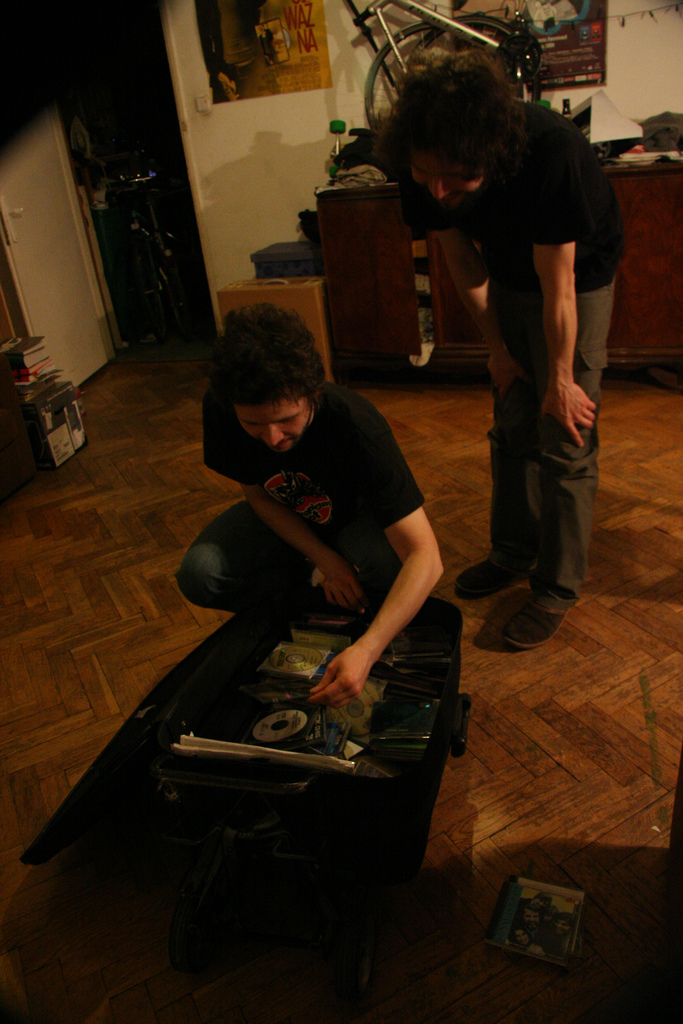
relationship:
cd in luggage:
[253, 710, 308, 743] [251, 608, 444, 769]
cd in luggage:
[258, 640, 331, 681] [229, 618, 442, 758]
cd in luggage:
[258, 640, 331, 681] [228, 587, 462, 820]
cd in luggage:
[195, 589, 416, 771] [195, 589, 416, 771]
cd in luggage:
[253, 710, 308, 743] [151, 573, 481, 850]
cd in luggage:
[253, 710, 308, 743] [145, 587, 481, 820]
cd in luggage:
[258, 640, 331, 681] [159, 608, 473, 823]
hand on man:
[524, 361, 616, 444] [404, 77, 616, 445]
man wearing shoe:
[388, 47, 625, 650] [496, 599, 584, 668]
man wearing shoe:
[380, 9, 662, 655] [461, 565, 558, 655]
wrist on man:
[317, 627, 397, 666] [165, 263, 397, 665]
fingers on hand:
[555, 398, 603, 442] [522, 141, 613, 448]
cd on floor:
[463, 854, 601, 988] [463, 793, 646, 989]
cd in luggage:
[274, 622, 428, 753] [274, 622, 428, 753]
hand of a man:
[288, 630, 379, 711] [188, 290, 379, 711]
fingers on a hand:
[308, 670, 351, 711] [296, 646, 351, 711]